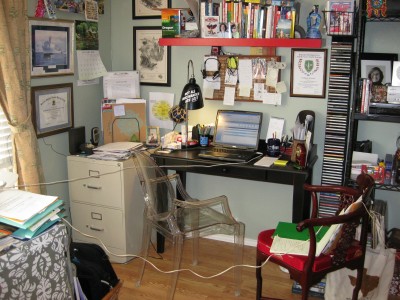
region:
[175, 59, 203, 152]
black lamp on top of desk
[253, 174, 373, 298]
heating pad in red chair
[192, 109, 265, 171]
black laptop on desk top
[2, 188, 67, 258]
stack of papers on grey table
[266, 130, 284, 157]
coffee cup with pencils in it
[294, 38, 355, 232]
large cd shelf beside of desk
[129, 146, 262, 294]
clear plastic chair in front of desk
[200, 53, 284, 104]
cork board on wall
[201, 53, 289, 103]
cork board on wall with papers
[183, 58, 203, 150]
Black lamp with its silver neck arched.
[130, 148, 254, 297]
Clear plastic chair at the computer desk.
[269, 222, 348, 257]
White laptop sitting open on a chair.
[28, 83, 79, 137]
Picture frame of a certificate hanging on the wall.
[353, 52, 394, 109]
Picture frame with a photo of a woman in it.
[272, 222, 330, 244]
Green folder sitting on a laptop.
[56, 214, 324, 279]
White cord stretched across the room.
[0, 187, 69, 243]
Stack of blue and white papers.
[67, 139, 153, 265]
Tan filing cabinet beside the computer desk.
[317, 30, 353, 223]
Black cd holder full of cd's.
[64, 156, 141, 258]
a white filing cabinet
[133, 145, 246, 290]
a clear chair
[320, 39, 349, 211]
a row of cds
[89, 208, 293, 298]
the floor is light brown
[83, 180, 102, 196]
it is a handle on the cabinet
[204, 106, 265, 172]
it is a black laptop computer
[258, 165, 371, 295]
it is a brown chair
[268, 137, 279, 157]
it is a blue coffee cup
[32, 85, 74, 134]
it is a picture on the wall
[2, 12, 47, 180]
the curtain is light brown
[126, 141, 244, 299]
clear plastic desk chair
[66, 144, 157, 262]
cream-colored, 2-drawer file cabinet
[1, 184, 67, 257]
pile of paperwork on table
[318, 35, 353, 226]
tall, slender CD case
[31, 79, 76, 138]
framed certificate on wall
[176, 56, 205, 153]
black, white and silver metal desk lamp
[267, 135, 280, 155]
coffee mug being used as a pencil cup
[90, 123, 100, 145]
black and silver cordless phone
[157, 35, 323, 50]
red, slender book shelf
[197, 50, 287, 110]
cork board filled with notes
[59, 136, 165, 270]
a cabin has two shelves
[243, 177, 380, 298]
the chair has a red cushion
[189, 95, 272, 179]
a laptop on a table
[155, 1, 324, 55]
the books on a shelf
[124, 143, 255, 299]
the chair is transparent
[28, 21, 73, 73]
the picture has black frame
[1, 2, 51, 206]
the curtain on front a window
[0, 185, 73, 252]
a stack of papers on a table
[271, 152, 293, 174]
sticky notes on a table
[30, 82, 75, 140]
a diploma is hanging on the wall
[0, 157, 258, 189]
a cable is hanging on the room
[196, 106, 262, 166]
the laptop is turned on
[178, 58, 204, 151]
the light is turned on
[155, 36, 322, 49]
the shelf is red in color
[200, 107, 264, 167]
the laptop is black in color